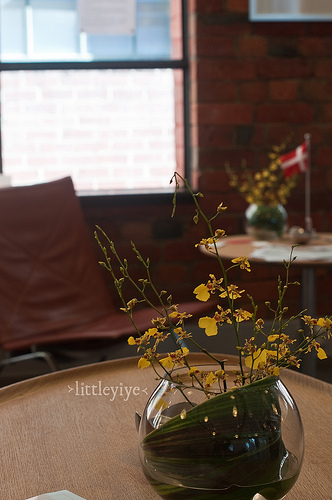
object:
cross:
[280, 142, 310, 176]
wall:
[80, 0, 332, 320]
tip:
[168, 172, 180, 219]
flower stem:
[170, 170, 258, 386]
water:
[144, 452, 298, 500]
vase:
[136, 364, 306, 499]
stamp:
[69, 376, 152, 402]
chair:
[0, 175, 220, 363]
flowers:
[121, 224, 331, 406]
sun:
[12, 25, 17, 34]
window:
[0, 0, 184, 194]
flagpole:
[295, 134, 319, 245]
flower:
[169, 322, 194, 344]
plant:
[95, 170, 332, 406]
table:
[0, 349, 332, 500]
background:
[0, 0, 332, 320]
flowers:
[232, 144, 300, 205]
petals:
[197, 314, 218, 339]